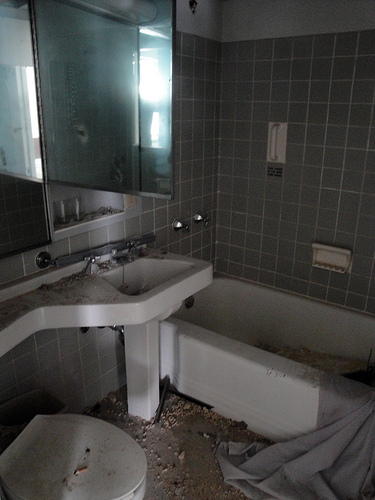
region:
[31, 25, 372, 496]
the scene is in a bathroom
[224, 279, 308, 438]
the bathtub is white in colour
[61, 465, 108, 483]
a ciggarate butt is on the seat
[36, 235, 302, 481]
the bathroom is in a mess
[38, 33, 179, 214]
a mirror is on the wall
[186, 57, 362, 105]
the wall is tilled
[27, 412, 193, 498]
the seat is shut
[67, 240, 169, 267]
the taps are silver in colour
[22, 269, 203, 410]
the sink is white in colour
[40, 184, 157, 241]
glasses are on the wall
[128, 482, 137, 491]
part of a toilet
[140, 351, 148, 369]
part of a sink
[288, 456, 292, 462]
part of a cloth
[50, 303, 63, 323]
part of a sink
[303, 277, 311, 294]
part of a wall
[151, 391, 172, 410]
edge of a sink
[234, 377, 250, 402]
part of a sink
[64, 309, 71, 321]
part of a mirror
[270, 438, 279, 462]
part of a curtain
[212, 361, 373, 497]
gray shower curtain draped over tub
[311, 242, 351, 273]
white soap holder built in to the wall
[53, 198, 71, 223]
clea glass cup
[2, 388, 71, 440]
empty gray trash can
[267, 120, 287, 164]
white support bar on the wall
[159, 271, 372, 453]
dirty white bath tub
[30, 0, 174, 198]
open medicine cabinet mirrored door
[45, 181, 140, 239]
white cubby hole above the sink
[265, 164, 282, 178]
small black lettering below support grip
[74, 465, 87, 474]
cigarette butt on toilet lid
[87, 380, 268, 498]
debris on bathroom floor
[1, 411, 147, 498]
closed cover of toilet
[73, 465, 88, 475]
cigarette but on toilet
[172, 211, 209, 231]
two medal handles on wall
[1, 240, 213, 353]
sink with curved vanity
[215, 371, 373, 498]
shower curtain over tub edge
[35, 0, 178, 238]
open mirror on cabinet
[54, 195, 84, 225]
two glasses on shelf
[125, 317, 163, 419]
white pedestal under sink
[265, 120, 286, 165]
white handle on plate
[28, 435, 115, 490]
a smoked cigarette on the toilet lid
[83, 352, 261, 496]
debris surrounding the sink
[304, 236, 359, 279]
a soap dish on the wall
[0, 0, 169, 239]
an opened medicine cabinet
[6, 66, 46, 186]
a door reflected in the mirror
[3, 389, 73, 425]
a trash can against the wall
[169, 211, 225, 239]
silver knobs in the shower area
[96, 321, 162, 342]
silver pipes behind the sink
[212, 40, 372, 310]
a wall of green tiles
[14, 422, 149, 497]
a closed toilet lid